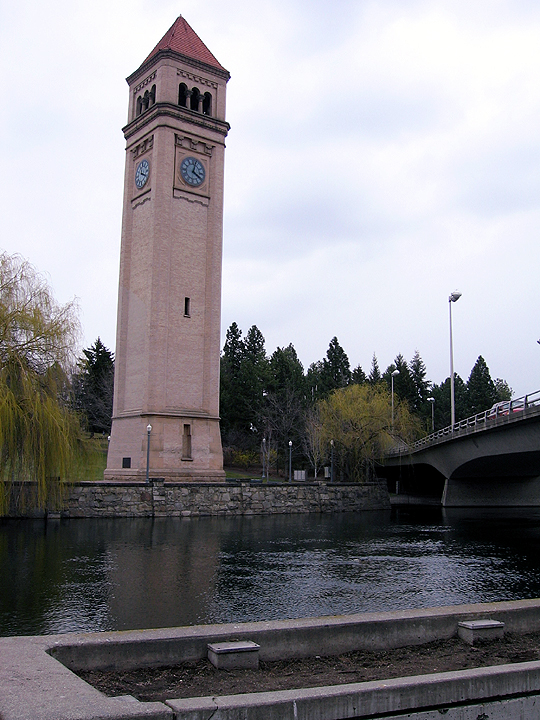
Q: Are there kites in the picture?
A: No, there are no kites.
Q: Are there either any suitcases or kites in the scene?
A: No, there are no kites or suitcases.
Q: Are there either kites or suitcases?
A: No, there are no kites or suitcases.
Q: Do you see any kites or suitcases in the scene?
A: No, there are no kites or suitcases.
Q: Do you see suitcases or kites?
A: No, there are no kites or suitcases.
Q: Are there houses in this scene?
A: No, there are no houses.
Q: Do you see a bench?
A: No, there are no benches.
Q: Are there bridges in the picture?
A: Yes, there is a bridge.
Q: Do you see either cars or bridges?
A: Yes, there is a bridge.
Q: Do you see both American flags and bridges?
A: No, there is a bridge but no American flags.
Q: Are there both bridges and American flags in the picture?
A: No, there is a bridge but no American flags.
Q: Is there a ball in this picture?
A: No, there are no balls.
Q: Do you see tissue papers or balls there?
A: No, there are no balls or tissue papers.